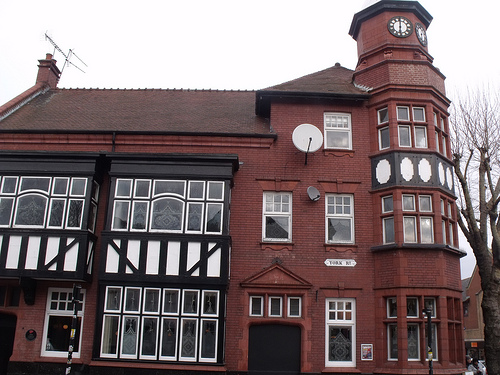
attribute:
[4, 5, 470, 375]
building — brick, red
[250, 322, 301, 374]
door — black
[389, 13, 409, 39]
clock — 6:00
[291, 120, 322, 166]
satellite dish — white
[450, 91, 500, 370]
tree — leafless, bare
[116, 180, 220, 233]
windows — stained white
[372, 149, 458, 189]
design — decorative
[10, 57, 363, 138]
roof — brown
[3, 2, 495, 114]
sky — cloudy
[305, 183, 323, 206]
satellite dish — gray, small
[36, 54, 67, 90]
chimney — brick